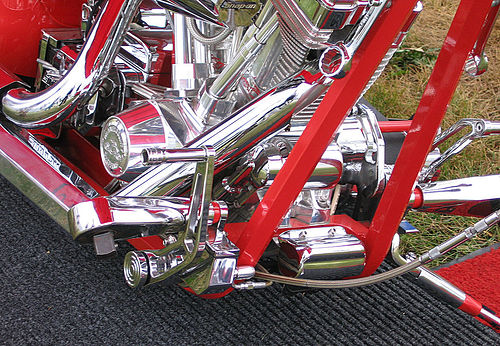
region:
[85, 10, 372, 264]
chrome on a motorcycle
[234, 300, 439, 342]
a black ridged mat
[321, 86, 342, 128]
a red metal bar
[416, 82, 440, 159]
a red metal bar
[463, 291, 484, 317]
red tape on a bar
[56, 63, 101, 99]
a reflection on the chrome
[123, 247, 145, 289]
a round metal screw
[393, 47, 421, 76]
a small dark green plant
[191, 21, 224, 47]
shiny metal tube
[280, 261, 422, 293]
a thick gray plastic tube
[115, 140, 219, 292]
silver chrome starter pedal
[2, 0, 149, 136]
silver chrome exhaust pipe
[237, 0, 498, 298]
red metal cycle frame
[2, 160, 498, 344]
black grooved carpet mat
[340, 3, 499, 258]
long brown and green grass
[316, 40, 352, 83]
silver metal wrench head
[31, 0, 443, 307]
shiny chrome cycle motor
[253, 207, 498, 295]
long narrow metal tubing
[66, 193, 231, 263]
metal chrome foot rest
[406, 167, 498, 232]
foot rest on right side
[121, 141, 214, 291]
A chrome colored foot pedal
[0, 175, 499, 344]
Some black carpeting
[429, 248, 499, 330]
Some red carpeting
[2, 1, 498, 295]
A red and chrome motorcycle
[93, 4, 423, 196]
A motorcycle engine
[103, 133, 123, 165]
some harley davidson branding on the motorcycle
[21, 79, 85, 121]
the reflection of people on the motorcycle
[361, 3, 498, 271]
A grassy landscape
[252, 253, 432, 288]
A flexible metal hose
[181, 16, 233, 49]
A flexible metal hose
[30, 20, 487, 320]
low view of motorcycle engine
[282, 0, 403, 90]
chrome-plated box-end wrench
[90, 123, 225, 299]
chromed foot rest of motorcycle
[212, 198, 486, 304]
brake line for motorcycle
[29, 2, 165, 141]
chrome-plated exhaust tube for motorcycle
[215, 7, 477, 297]
suspension struts for motorcycle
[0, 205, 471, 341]
black and gray mat below motorcycle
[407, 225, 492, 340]
red mat below motorcycle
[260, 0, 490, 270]
green turf near motorcycle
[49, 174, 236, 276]
chrome-plated ratchet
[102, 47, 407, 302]
transmission of a motorcycle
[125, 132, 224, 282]
rear break of a motorcycle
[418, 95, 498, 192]
gear selector of the motorcycle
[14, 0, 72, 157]
red paint on the motorcycle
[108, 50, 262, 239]
chrome parts on the engine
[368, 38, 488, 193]
grass behind the motorcycle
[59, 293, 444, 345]
dark black carpet underneath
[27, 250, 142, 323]
grooves in the carpet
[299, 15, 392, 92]
wrench hanging off bike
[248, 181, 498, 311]
cable coming from the bottom